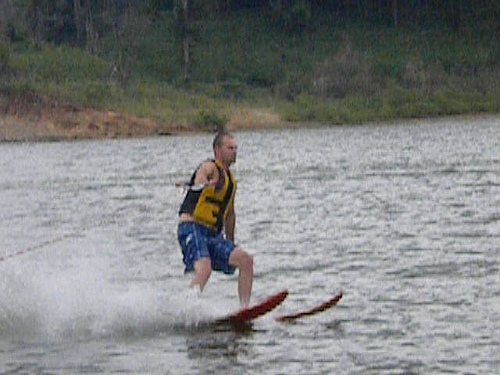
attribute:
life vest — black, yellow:
[180, 160, 234, 232]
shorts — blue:
[173, 220, 239, 277]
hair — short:
[211, 128, 235, 148]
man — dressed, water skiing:
[177, 131, 260, 307]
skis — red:
[206, 289, 289, 321]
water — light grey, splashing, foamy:
[0, 107, 499, 374]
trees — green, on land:
[3, 0, 499, 140]